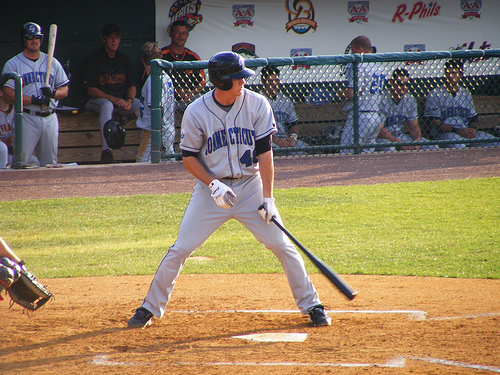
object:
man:
[127, 48, 332, 328]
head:
[207, 51, 256, 97]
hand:
[207, 177, 237, 209]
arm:
[179, 100, 237, 210]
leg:
[244, 181, 331, 327]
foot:
[309, 304, 332, 326]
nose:
[238, 77, 246, 86]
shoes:
[127, 304, 332, 329]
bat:
[258, 204, 359, 301]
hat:
[208, 51, 257, 91]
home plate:
[228, 330, 311, 346]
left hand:
[258, 197, 279, 225]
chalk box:
[91, 304, 429, 368]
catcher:
[0, 235, 51, 311]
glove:
[5, 267, 51, 311]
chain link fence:
[149, 49, 500, 162]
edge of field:
[0, 145, 499, 176]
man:
[1, 20, 70, 167]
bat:
[41, 24, 58, 109]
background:
[0, 1, 499, 169]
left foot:
[128, 306, 154, 329]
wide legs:
[128, 178, 333, 327]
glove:
[257, 198, 279, 225]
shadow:
[1, 323, 316, 369]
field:
[15, 145, 499, 373]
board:
[155, 1, 500, 85]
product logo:
[230, 1, 257, 30]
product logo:
[283, 1, 318, 35]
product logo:
[345, 1, 371, 24]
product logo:
[390, 1, 443, 25]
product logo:
[458, 0, 484, 19]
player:
[425, 60, 494, 145]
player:
[375, 67, 439, 149]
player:
[258, 64, 309, 149]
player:
[84, 24, 138, 166]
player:
[141, 21, 205, 97]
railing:
[150, 47, 498, 160]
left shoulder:
[242, 89, 278, 129]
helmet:
[21, 21, 44, 47]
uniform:
[428, 80, 499, 147]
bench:
[0, 95, 499, 168]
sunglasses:
[24, 33, 40, 40]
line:
[426, 312, 500, 324]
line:
[417, 352, 499, 374]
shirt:
[178, 88, 279, 179]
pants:
[141, 176, 322, 320]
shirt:
[1, 51, 71, 111]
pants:
[10, 108, 58, 168]